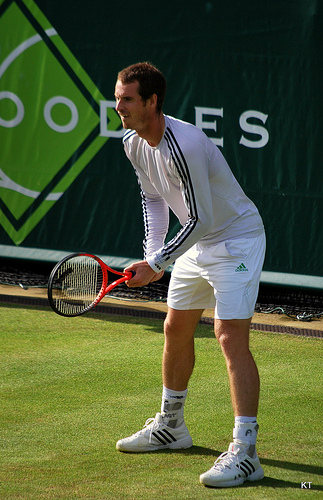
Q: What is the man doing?
A: Playing tennis.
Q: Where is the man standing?
A: On a tennis court.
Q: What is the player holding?
A: Tennis racket.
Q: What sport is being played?
A: Tennis.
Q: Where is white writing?
A: On green wall.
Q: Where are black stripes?
A: On white shirt.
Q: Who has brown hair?
A: Tennis player.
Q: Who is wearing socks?
A: The player.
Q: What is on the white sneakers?
A: Black stripes.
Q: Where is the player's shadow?
A: On the court.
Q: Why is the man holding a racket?
A: To hit the ball.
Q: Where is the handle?
A: On racket.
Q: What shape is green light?
A: Triangle.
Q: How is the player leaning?
A: Forward.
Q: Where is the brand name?
A: On shorts.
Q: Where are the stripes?
A: On shirt.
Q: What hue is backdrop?
A: Green.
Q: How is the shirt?
A: Long sleeved.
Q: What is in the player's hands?
A: Tennis racket.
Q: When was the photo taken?
A: In the daytime.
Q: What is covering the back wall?
A: Green fabric.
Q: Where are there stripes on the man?
A: His sleeves.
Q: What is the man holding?
A: Tennis racket.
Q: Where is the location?
A: Tennis court.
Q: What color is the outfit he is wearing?
A: White.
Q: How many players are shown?
A: One.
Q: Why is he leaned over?
A: Ready to hit the ball.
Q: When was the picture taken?
A: Daytime.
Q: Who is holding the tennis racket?
A: Tennis player.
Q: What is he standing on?
A: Turf.